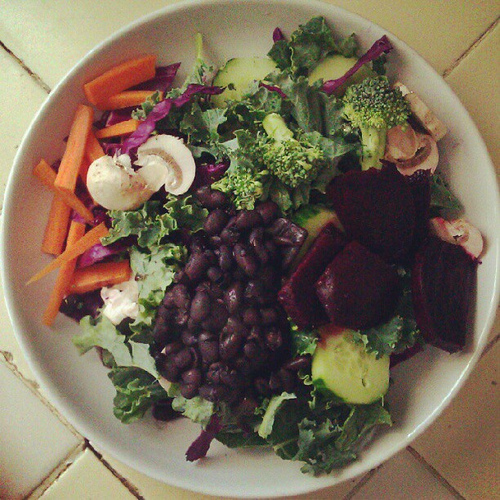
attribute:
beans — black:
[193, 273, 279, 318]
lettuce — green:
[202, 46, 289, 93]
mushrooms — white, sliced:
[72, 134, 211, 199]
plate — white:
[210, 0, 217, 9]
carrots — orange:
[76, 49, 154, 97]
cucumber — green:
[325, 363, 391, 399]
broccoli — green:
[210, 126, 319, 168]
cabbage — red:
[332, 264, 400, 322]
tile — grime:
[0, 34, 42, 83]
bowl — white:
[432, 49, 475, 128]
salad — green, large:
[64, 110, 365, 267]